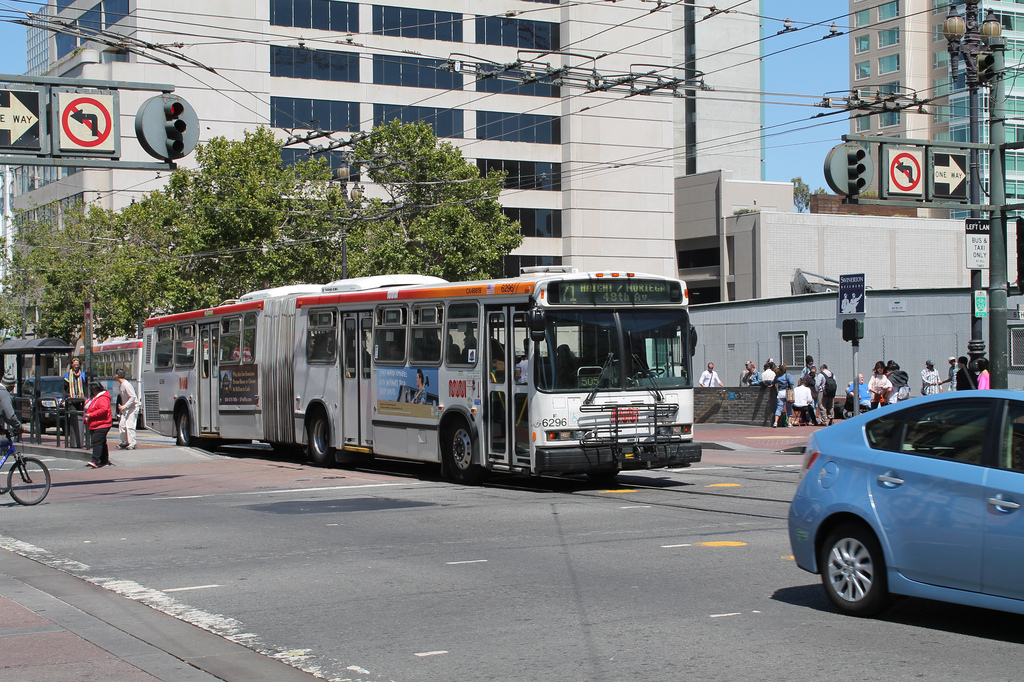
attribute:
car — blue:
[782, 384, 1021, 622]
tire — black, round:
[778, 500, 900, 624]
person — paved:
[80, 380, 110, 473]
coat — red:
[78, 387, 116, 436]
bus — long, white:
[131, 262, 702, 500]